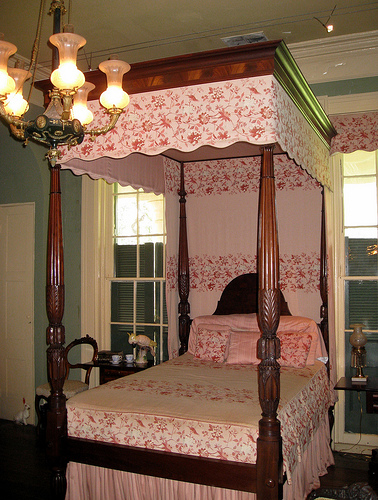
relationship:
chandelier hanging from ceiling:
[7, 0, 131, 169] [1, 1, 377, 71]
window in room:
[106, 176, 170, 358] [1, 1, 378, 499]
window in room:
[340, 147, 378, 439] [1, 1, 378, 499]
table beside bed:
[334, 369, 377, 415] [31, 40, 336, 498]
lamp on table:
[348, 320, 370, 384] [334, 369, 377, 415]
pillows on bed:
[193, 326, 313, 369] [31, 40, 336, 498]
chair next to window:
[34, 332, 99, 439] [106, 176, 170, 358]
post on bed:
[254, 142, 287, 500] [31, 40, 336, 498]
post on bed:
[42, 147, 71, 500] [31, 40, 336, 498]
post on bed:
[177, 161, 193, 353] [31, 40, 336, 498]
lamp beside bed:
[348, 320, 370, 384] [31, 40, 336, 498]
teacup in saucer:
[111, 353, 122, 362] [109, 359, 124, 364]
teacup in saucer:
[127, 353, 136, 362] [122, 358, 135, 363]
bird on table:
[128, 330, 158, 368] [85, 357, 154, 385]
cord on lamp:
[338, 389, 374, 462] [348, 320, 370, 384]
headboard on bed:
[208, 273, 292, 317] [31, 40, 336, 498]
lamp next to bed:
[348, 320, 370, 384] [31, 40, 336, 498]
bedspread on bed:
[67, 351, 338, 482] [31, 40, 336, 498]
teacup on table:
[111, 353, 122, 362] [85, 357, 154, 385]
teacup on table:
[127, 353, 136, 362] [85, 357, 154, 385]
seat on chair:
[34, 379, 89, 398] [34, 332, 99, 439]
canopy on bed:
[35, 40, 335, 189] [31, 40, 336, 498]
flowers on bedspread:
[102, 377, 285, 414] [67, 351, 338, 482]